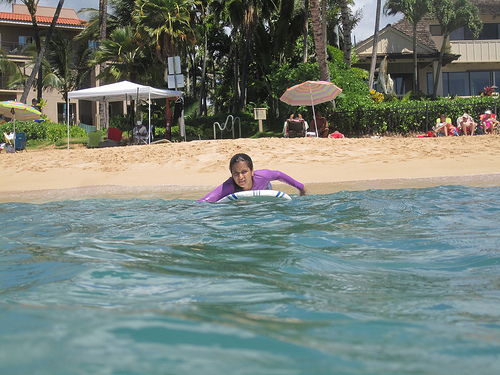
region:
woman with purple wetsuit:
[203, 154, 308, 199]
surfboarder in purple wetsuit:
[201, 156, 313, 198]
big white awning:
[68, 72, 192, 151]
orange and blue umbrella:
[280, 77, 340, 130]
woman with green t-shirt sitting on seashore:
[434, 114, 456, 134]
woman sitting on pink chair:
[479, 110, 498, 130]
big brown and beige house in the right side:
[342, 11, 497, 98]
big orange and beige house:
[0, 5, 101, 130]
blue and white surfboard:
[216, 188, 288, 203]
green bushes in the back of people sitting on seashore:
[351, 97, 498, 126]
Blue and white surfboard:
[208, 190, 296, 202]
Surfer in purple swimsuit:
[191, 153, 306, 214]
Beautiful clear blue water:
[3, 179, 498, 373]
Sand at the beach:
[3, 140, 498, 197]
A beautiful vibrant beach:
[4, 13, 495, 360]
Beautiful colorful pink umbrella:
[271, 80, 345, 138]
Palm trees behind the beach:
[11, 0, 481, 127]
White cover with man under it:
[58, 81, 202, 148]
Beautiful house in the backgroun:
[338, 3, 499, 115]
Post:
[250, 104, 269, 131]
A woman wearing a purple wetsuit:
[187, 144, 314, 218]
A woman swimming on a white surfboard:
[196, 147, 308, 213]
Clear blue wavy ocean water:
[69, 218, 487, 359]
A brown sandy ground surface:
[23, 154, 172, 186]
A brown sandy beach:
[26, 159, 181, 195]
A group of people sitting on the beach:
[428, 99, 498, 146]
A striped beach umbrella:
[268, 76, 350, 116]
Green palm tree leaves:
[94, 21, 152, 76]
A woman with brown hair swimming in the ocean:
[186, 153, 321, 220]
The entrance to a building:
[335, 14, 467, 110]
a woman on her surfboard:
[197, 150, 309, 215]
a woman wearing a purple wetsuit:
[191, 151, 307, 223]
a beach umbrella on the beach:
[279, 78, 341, 140]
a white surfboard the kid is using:
[216, 190, 291, 205]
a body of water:
[46, 220, 496, 338]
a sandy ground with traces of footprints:
[96, 147, 198, 171]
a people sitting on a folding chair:
[432, 106, 496, 145]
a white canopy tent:
[64, 79, 186, 150]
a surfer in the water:
[194, 151, 308, 211]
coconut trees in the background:
[86, 4, 321, 71]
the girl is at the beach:
[1, 2, 496, 371]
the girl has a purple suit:
[208, 170, 305, 197]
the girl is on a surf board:
[216, 188, 291, 203]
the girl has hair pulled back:
[231, 155, 253, 175]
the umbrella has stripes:
[286, 77, 341, 136]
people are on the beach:
[0, 118, 497, 153]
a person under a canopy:
[65, 80, 187, 142]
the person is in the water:
[201, 153, 306, 203]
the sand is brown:
[2, 133, 498, 200]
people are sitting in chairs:
[278, 111, 498, 138]